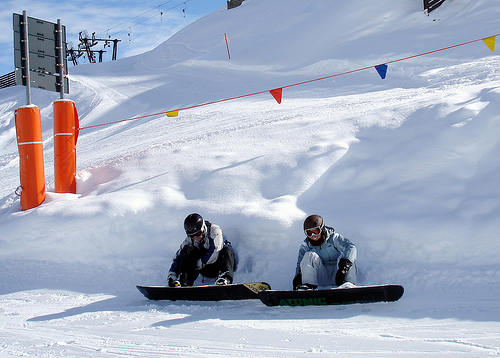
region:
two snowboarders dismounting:
[134, 200, 414, 318]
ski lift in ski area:
[3, 8, 495, 170]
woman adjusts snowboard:
[267, 214, 406, 309]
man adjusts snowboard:
[125, 200, 260, 301]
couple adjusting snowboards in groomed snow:
[1, 168, 421, 357]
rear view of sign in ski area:
[12, 13, 101, 221]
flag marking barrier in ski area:
[41, 62, 482, 179]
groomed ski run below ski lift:
[6, 5, 490, 208]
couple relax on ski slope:
[129, 194, 434, 353]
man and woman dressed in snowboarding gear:
[128, 198, 409, 342]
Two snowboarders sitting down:
[133, 211, 406, 311]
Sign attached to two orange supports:
[6, 9, 88, 206]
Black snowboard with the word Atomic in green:
[256, 285, 403, 308]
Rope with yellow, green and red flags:
[84, 32, 499, 126]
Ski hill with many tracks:
[4, 7, 496, 353]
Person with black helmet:
[134, 208, 273, 304]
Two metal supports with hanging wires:
[68, 8, 215, 66]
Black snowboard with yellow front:
[131, 278, 273, 302]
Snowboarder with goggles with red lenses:
[256, 207, 406, 309]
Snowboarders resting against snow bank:
[5, 95, 498, 307]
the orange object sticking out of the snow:
[12, 103, 46, 210]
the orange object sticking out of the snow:
[51, 98, 78, 193]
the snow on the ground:
[0, 1, 497, 356]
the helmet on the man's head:
[303, 215, 323, 227]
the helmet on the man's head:
[183, 214, 203, 231]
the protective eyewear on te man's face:
[304, 226, 322, 237]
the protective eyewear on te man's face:
[181, 226, 204, 238]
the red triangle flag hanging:
[270, 88, 282, 104]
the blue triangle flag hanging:
[375, 63, 387, 78]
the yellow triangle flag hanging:
[482, 34, 495, 51]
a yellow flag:
[161, 102, 184, 128]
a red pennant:
[265, 79, 285, 106]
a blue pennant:
[369, 51, 397, 89]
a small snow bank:
[142, 117, 464, 214]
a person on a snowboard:
[249, 202, 402, 316]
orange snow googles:
[303, 225, 323, 236]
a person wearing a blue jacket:
[294, 200, 364, 309]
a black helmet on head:
[181, 212, 204, 231]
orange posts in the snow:
[6, 102, 86, 199]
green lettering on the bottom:
[279, 295, 334, 309]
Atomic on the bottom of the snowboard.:
[272, 287, 340, 314]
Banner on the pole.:
[48, 33, 498, 143]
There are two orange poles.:
[6, 89, 86, 198]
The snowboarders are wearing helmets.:
[171, 209, 337, 244]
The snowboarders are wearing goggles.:
[177, 223, 337, 250]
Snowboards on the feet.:
[133, 271, 422, 320]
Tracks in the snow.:
[48, 329, 320, 356]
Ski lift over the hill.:
[58, 19, 133, 74]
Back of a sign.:
[4, 10, 79, 116]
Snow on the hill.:
[1, 2, 498, 347]